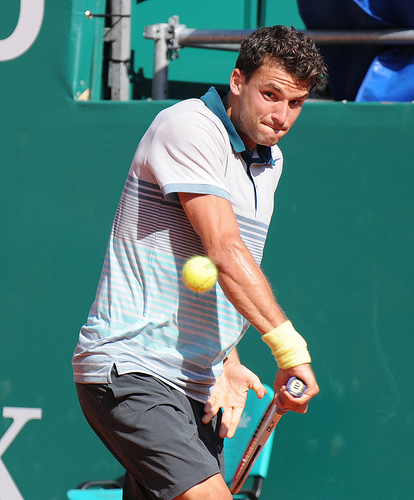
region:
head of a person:
[221, 30, 333, 150]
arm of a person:
[167, 212, 304, 332]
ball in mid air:
[147, 257, 234, 307]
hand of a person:
[274, 352, 333, 402]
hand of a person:
[191, 359, 264, 431]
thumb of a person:
[250, 365, 279, 406]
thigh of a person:
[80, 386, 201, 496]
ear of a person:
[219, 65, 261, 96]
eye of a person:
[252, 89, 274, 108]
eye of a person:
[284, 91, 319, 109]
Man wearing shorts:
[69, 362, 246, 498]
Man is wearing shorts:
[75, 356, 234, 497]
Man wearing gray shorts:
[72, 365, 228, 497]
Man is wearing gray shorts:
[71, 366, 233, 498]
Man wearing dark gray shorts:
[70, 356, 230, 498]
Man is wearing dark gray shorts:
[72, 357, 232, 497]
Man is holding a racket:
[222, 371, 310, 496]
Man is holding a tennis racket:
[221, 370, 308, 493]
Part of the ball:
[195, 265, 206, 282]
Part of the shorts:
[148, 415, 167, 442]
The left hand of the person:
[199, 357, 267, 437]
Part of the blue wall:
[334, 253, 371, 334]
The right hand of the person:
[269, 354, 321, 414]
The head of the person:
[226, 21, 330, 148]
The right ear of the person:
[227, 66, 243, 96]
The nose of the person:
[269, 98, 289, 125]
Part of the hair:
[270, 36, 285, 49]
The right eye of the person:
[260, 87, 279, 101]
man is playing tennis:
[2, 2, 412, 495]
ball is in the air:
[181, 250, 222, 300]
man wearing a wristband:
[246, 315, 311, 372]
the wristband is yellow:
[260, 309, 314, 369]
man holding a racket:
[218, 367, 310, 498]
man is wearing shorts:
[72, 363, 228, 497]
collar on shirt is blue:
[203, 81, 278, 168]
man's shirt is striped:
[73, 86, 288, 399]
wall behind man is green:
[1, 3, 409, 498]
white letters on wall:
[3, 1, 66, 498]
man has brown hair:
[232, 36, 327, 102]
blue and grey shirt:
[123, 108, 278, 380]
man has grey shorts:
[72, 375, 229, 493]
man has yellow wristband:
[274, 322, 311, 388]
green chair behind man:
[189, 394, 306, 489]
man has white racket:
[217, 391, 286, 467]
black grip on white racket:
[268, 368, 304, 414]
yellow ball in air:
[174, 242, 224, 312]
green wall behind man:
[11, 142, 141, 292]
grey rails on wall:
[88, 2, 410, 75]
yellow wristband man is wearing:
[260, 311, 311, 369]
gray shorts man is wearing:
[89, 368, 235, 494]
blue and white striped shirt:
[70, 89, 273, 390]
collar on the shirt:
[203, 84, 281, 165]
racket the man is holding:
[223, 372, 312, 497]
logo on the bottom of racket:
[281, 368, 325, 401]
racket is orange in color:
[234, 380, 308, 492]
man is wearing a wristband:
[259, 302, 322, 373]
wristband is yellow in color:
[261, 312, 315, 374]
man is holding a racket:
[254, 333, 321, 478]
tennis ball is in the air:
[160, 231, 228, 301]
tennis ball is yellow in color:
[178, 240, 225, 299]